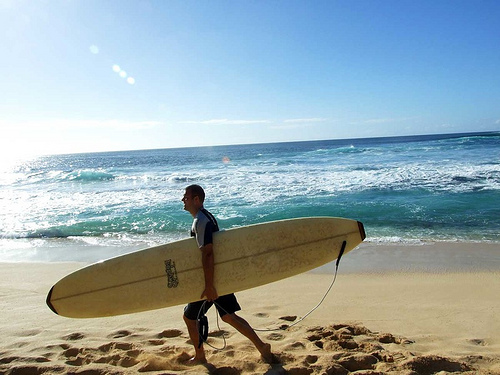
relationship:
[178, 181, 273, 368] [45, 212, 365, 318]
man carrying surfboard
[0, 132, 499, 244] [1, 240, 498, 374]
ocean against beach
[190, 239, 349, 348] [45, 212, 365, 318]
rope on surfboard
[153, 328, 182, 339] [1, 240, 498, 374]
footprint on beach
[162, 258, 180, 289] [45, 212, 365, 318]
logo on surfboard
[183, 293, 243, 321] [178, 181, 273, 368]
shorts on man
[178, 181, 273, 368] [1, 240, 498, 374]
man on beach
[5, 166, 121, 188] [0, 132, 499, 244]
wave in ocean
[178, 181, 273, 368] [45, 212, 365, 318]
man has h surfboard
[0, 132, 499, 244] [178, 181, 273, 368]
ocean behind man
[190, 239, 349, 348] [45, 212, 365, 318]
rope connected to surfboard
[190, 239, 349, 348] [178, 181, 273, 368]
rope on man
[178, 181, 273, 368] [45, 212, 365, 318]
man carrying a white surfboard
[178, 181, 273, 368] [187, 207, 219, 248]
man in a shirt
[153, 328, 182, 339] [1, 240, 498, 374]
footprint in beach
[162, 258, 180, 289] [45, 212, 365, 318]
logo on white surfboard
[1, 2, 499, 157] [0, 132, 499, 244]
sky meets ocean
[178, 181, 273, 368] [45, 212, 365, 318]
man holding surfboard